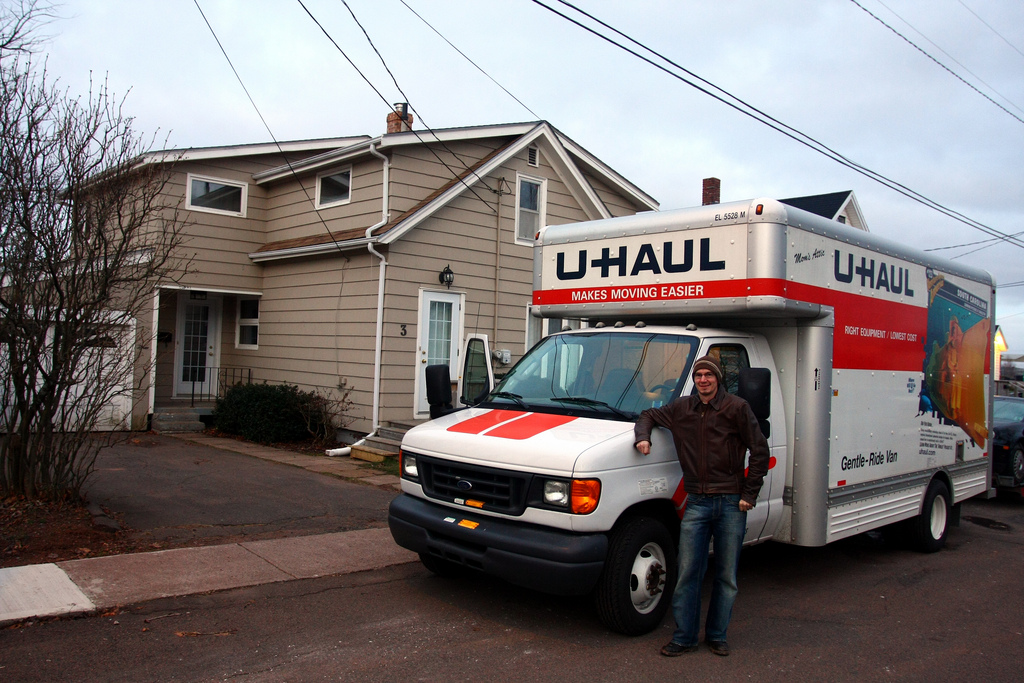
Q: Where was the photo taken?
A: At a house.